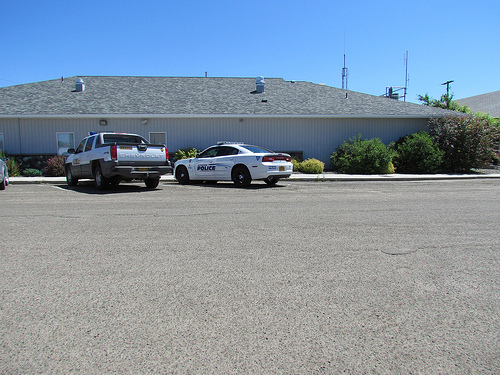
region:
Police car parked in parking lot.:
[171, 136, 299, 199]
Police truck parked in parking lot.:
[46, 124, 176, 196]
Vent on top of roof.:
[238, 66, 278, 100]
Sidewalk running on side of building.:
[316, 167, 493, 190]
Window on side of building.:
[50, 125, 79, 157]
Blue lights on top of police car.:
[206, 133, 257, 147]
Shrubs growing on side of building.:
[332, 96, 499, 178]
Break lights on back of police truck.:
[105, 140, 177, 166]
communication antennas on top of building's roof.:
[336, 16, 416, 107]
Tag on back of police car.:
[277, 162, 293, 180]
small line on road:
[370, 237, 432, 265]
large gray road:
[65, 276, 305, 336]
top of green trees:
[420, 85, 476, 111]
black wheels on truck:
[88, 159, 130, 209]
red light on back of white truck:
[96, 138, 168, 158]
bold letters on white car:
[190, 161, 235, 178]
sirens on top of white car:
[213, 134, 258, 149]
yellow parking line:
[43, 162, 133, 173]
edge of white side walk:
[341, 174, 368, 188]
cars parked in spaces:
[68, 98, 352, 203]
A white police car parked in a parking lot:
[170, 147, 291, 177]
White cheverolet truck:
[50, 125, 186, 197]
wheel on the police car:
[230, 162, 248, 182]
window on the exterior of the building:
[53, 130, 69, 153]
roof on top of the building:
[0, 77, 456, 117]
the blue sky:
[15, 25, 311, 70]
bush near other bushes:
[331, 140, 391, 171]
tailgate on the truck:
[113, 143, 168, 159]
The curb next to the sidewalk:
[290, 175, 411, 180]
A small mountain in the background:
[462, 88, 498, 117]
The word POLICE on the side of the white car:
[195, 166, 218, 172]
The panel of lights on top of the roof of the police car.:
[218, 136, 248, 147]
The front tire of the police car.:
[176, 161, 190, 179]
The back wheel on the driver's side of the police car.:
[230, 164, 252, 185]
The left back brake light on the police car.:
[263, 153, 273, 162]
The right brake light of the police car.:
[283, 157, 298, 161]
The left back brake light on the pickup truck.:
[109, 148, 119, 160]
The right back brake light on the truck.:
[163, 148, 170, 159]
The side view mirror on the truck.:
[66, 146, 77, 156]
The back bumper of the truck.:
[107, 161, 172, 173]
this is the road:
[187, 202, 442, 342]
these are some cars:
[62, 125, 295, 190]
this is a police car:
[174, 143, 292, 186]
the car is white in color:
[223, 153, 237, 163]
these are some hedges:
[335, 132, 439, 172]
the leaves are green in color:
[345, 150, 435, 165]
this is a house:
[290, 80, 350, 172]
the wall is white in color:
[282, 120, 319, 142]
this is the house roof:
[143, 81, 201, 108]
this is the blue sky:
[153, 14, 262, 59]